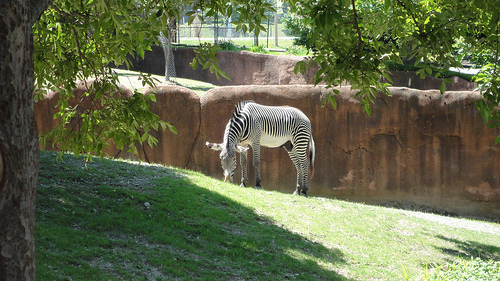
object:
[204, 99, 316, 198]
zebra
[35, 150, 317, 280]
grass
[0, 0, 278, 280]
trees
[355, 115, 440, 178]
rock